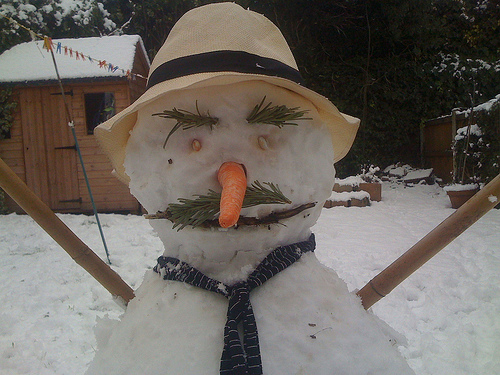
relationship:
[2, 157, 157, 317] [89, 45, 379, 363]
stick left side of snowman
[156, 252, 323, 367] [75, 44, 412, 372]
tie on snowman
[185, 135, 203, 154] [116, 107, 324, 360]
eye of snowman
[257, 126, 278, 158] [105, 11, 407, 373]
eye of a snowman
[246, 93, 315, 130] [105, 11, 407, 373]
eyebrow of a snowman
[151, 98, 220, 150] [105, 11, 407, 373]
eyebrow of a snowman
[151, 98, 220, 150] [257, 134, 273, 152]
eyebrow of a eye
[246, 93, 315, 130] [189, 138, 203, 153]
eyebrow of a eye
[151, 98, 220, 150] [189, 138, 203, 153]
eyebrow of a eye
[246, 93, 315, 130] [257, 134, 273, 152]
eyebrow of a eye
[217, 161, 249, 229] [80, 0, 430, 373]
carrot of a snowman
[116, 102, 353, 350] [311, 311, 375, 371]
snowman in snow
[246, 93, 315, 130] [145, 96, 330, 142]
eyebrow made of pine needles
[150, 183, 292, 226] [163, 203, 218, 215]
moustache made of pine needles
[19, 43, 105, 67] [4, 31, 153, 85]
snow on roof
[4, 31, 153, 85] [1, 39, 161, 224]
roof of building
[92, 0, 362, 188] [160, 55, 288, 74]
hat with a band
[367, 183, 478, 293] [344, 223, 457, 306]
wooden pole stuck in snow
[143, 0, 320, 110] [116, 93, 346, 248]
hat on snowman's head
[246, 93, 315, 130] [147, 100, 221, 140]
eyebrow as an eyebrow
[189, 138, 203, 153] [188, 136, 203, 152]
eye as eye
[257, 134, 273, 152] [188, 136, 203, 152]
eye as eye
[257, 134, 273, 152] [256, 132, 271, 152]
eye as eye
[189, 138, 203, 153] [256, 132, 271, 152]
eye as eye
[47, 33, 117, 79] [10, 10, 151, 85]
clothespins on a laundry line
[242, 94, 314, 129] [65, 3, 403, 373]
eyebrow on a snowman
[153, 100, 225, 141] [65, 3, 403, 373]
eyebrow on a snowman